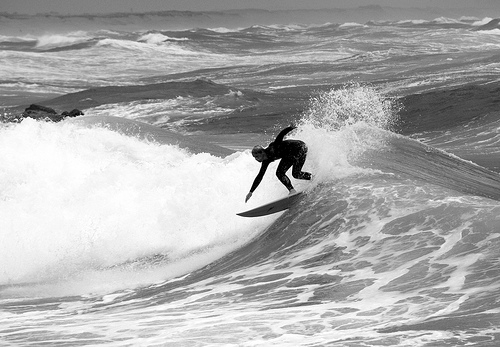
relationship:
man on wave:
[245, 121, 322, 204] [1, 114, 499, 307]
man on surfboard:
[245, 121, 322, 204] [236, 188, 307, 218]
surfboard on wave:
[236, 188, 307, 218] [1, 114, 499, 307]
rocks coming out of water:
[3, 104, 84, 123] [1, 0, 499, 346]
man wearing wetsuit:
[245, 121, 322, 204] [247, 126, 313, 191]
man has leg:
[245, 121, 322, 204] [292, 151, 314, 180]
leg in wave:
[292, 151, 314, 180] [1, 114, 499, 307]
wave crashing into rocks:
[1, 114, 499, 307] [3, 104, 84, 123]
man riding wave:
[245, 121, 322, 204] [1, 114, 499, 307]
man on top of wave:
[245, 121, 322, 204] [1, 114, 499, 307]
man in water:
[245, 121, 322, 204] [1, 0, 499, 346]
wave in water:
[1, 114, 499, 307] [1, 0, 499, 346]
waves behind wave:
[0, 14, 499, 42] [1, 114, 499, 307]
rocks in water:
[3, 104, 84, 123] [1, 0, 499, 346]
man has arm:
[245, 121, 322, 204] [244, 160, 268, 203]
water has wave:
[1, 0, 499, 346] [1, 114, 499, 307]